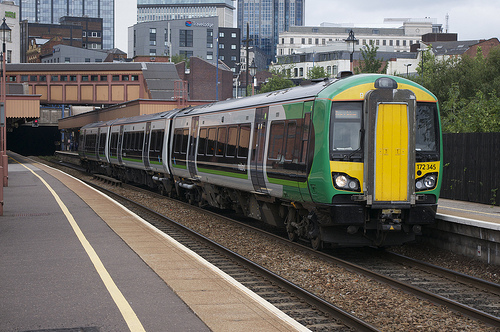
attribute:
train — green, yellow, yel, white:
[82, 72, 439, 249]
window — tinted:
[331, 100, 365, 152]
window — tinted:
[269, 122, 286, 162]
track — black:
[21, 160, 380, 329]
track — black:
[59, 158, 499, 324]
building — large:
[128, 18, 219, 77]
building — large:
[62, 15, 104, 60]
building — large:
[271, 51, 353, 80]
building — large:
[0, 0, 22, 66]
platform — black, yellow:
[1, 148, 309, 330]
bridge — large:
[0, 64, 187, 103]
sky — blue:
[3, 0, 499, 51]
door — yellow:
[376, 103, 408, 200]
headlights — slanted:
[331, 172, 442, 191]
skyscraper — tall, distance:
[237, 2, 305, 69]